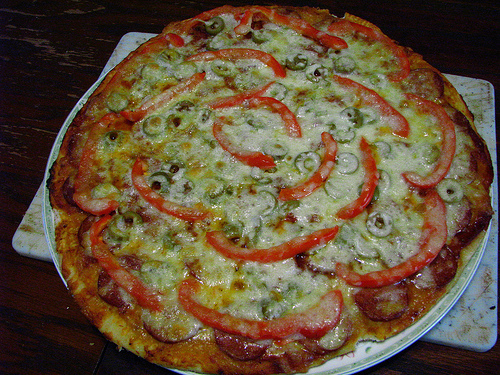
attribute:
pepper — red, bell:
[69, 110, 130, 218]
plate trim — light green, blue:
[352, 344, 397, 361]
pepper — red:
[332, 16, 412, 81]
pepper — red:
[331, 188, 455, 281]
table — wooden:
[1, 4, 494, 371]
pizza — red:
[154, 45, 415, 282]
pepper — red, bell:
[201, 219, 342, 268]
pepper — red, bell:
[87, 215, 163, 313]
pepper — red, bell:
[207, 92, 302, 139]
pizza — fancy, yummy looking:
[45, 0, 496, 370]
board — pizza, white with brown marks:
[9, 29, 499, 352]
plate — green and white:
[302, 208, 499, 374]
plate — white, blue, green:
[49, 22, 486, 368]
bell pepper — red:
[401, 90, 456, 188]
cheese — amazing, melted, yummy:
[47, 16, 492, 371]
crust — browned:
[60, 309, 232, 374]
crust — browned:
[48, 111, 92, 294]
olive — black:
[337, 150, 359, 175]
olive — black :
[294, 149, 323, 176]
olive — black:
[441, 182, 465, 202]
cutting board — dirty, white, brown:
[10, 28, 484, 352]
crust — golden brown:
[46, 0, 485, 372]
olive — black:
[285, 50, 311, 72]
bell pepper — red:
[333, 134, 381, 221]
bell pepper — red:
[167, 268, 350, 342]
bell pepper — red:
[222, 16, 345, 62]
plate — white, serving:
[26, 4, 494, 366]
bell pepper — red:
[130, 69, 205, 128]